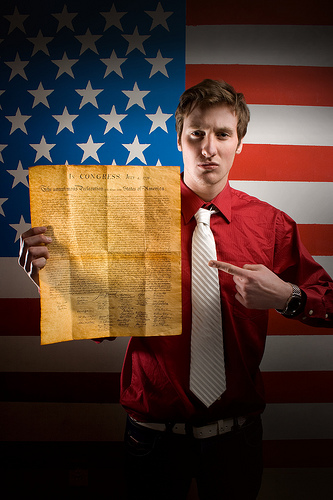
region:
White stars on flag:
[119, 27, 174, 84]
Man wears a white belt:
[123, 413, 257, 436]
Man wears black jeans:
[125, 444, 259, 488]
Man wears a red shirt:
[123, 348, 184, 397]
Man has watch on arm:
[282, 281, 304, 329]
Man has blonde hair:
[181, 76, 243, 107]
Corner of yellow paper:
[173, 303, 184, 337]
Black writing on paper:
[104, 291, 168, 320]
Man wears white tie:
[189, 207, 231, 411]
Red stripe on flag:
[5, 362, 120, 416]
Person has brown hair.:
[172, 88, 245, 111]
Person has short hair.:
[158, 67, 268, 153]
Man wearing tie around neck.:
[183, 204, 228, 409]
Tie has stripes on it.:
[185, 367, 225, 394]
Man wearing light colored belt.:
[174, 413, 248, 449]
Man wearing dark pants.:
[132, 465, 197, 486]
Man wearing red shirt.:
[146, 376, 174, 408]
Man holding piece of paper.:
[39, 137, 207, 314]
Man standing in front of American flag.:
[73, 92, 306, 269]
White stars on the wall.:
[35, 60, 136, 139]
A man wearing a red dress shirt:
[98, 74, 312, 408]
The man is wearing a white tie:
[179, 202, 227, 414]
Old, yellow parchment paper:
[21, 157, 192, 344]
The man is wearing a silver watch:
[274, 270, 305, 322]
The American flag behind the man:
[23, 9, 308, 450]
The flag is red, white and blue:
[23, 7, 296, 270]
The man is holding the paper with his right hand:
[23, 73, 312, 398]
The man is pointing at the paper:
[19, 75, 325, 400]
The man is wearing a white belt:
[117, 393, 273, 456]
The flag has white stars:
[5, 12, 183, 228]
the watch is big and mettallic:
[280, 277, 309, 328]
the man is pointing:
[112, 73, 327, 474]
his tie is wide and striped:
[184, 207, 226, 417]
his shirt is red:
[223, 209, 324, 404]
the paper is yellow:
[31, 160, 192, 344]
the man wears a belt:
[129, 397, 258, 443]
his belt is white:
[131, 406, 247, 444]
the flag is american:
[13, 9, 329, 79]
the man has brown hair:
[195, 80, 242, 110]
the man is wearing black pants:
[120, 432, 273, 493]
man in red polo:
[77, 177, 295, 387]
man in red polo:
[153, 82, 280, 280]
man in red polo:
[130, 71, 246, 340]